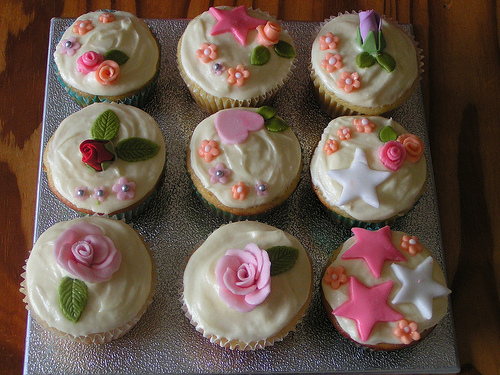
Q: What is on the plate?
A: Cupcakes.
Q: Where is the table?
A: In the room.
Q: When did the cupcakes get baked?
A: Today.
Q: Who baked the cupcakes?
A: The baker.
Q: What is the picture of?
A: Nine cupcakes.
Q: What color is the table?
A: Brown.